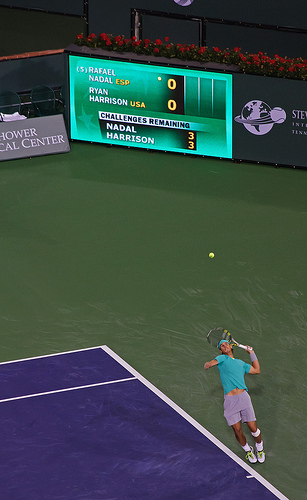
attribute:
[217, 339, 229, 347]
headband — blue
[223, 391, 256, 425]
shorts — grey, gray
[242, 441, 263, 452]
socks — white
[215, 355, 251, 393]
t-shirt — blue, teal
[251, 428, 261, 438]
leg wrap — white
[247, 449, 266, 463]
shoes — white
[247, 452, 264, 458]
laces — yellow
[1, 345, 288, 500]
tennis court — blue, light purple, green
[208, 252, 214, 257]
tennis ball — yellow, in mid-air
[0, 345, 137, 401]
lines — white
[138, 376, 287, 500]
line — white, solid, edge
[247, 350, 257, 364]
band — purple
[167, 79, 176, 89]
number — yellow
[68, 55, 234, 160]
board — digital, for score, green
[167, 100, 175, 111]
number — yellow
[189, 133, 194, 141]
number — yellow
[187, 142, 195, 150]
number — yellow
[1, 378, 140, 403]
line — small, white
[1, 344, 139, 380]
edge — solid, white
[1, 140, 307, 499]
exterior — asphalt, green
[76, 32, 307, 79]
flowers — row, red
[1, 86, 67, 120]
objects — chairs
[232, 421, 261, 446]
legs — very tan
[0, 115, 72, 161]
sign — in background, grey